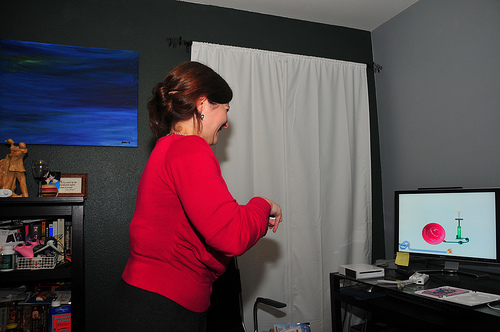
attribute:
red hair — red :
[142, 52, 239, 143]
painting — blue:
[0, 44, 153, 147]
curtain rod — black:
[172, 38, 196, 49]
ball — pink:
[417, 218, 446, 245]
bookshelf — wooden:
[1, 196, 85, 329]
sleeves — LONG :
[175, 139, 275, 262]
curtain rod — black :
[169, 33, 394, 81]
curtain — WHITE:
[169, 33, 410, 329]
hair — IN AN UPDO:
[142, 66, 207, 126]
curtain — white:
[188, 43, 376, 329]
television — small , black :
[397, 187, 499, 277]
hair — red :
[149, 59, 235, 131]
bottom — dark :
[111, 283, 214, 324]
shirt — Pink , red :
[125, 133, 270, 319]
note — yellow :
[390, 250, 410, 268]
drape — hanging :
[189, 42, 380, 328]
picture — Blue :
[3, 40, 144, 150]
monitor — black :
[391, 189, 497, 278]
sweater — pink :
[121, 133, 271, 312]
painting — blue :
[3, 37, 143, 151]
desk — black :
[329, 260, 494, 329]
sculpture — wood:
[0, 138, 30, 198]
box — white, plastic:
[11, 253, 56, 272]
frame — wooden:
[59, 172, 84, 198]